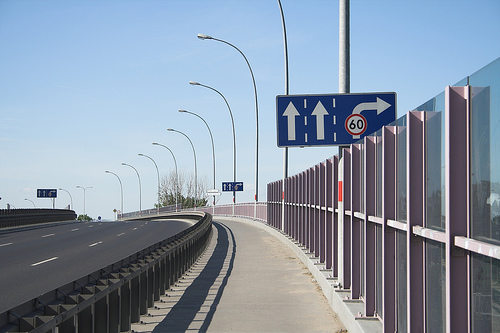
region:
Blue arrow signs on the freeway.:
[271, 85, 384, 146]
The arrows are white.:
[284, 98, 317, 135]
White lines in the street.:
[43, 227, 124, 259]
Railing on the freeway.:
[81, 216, 213, 280]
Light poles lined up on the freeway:
[128, 106, 326, 188]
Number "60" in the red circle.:
[344, 113, 367, 143]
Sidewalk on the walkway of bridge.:
[221, 195, 331, 331]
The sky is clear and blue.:
[44, 30, 229, 91]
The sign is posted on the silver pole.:
[268, 17, 400, 136]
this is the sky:
[21, 5, 84, 49]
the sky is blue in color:
[45, 7, 135, 50]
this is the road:
[43, 226, 116, 254]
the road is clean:
[50, 218, 134, 249]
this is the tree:
[157, 178, 229, 214]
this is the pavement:
[240, 241, 269, 313]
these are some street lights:
[133, 0, 306, 175]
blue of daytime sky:
[9, 2, 496, 214]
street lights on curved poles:
[107, 0, 350, 210]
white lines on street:
[0, 218, 189, 299]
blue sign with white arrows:
[275, 91, 396, 146]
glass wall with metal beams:
[269, 64, 495, 330]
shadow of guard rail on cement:
[166, 214, 237, 331]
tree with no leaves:
[163, 174, 214, 211]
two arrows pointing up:
[281, 98, 327, 141]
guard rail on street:
[13, 207, 213, 331]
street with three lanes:
[0, 218, 187, 313]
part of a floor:
[266, 252, 282, 279]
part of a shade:
[222, 251, 236, 273]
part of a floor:
[241, 254, 282, 320]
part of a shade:
[185, 240, 246, 311]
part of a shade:
[202, 258, 244, 308]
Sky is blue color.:
[49, 38, 137, 135]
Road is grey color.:
[15, 215, 133, 302]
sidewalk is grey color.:
[205, 208, 307, 328]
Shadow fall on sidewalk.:
[137, 218, 253, 331]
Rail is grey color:
[76, 250, 187, 329]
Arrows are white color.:
[218, 73, 405, 198]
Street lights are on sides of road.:
[86, 40, 368, 226]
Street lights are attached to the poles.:
[121, 33, 358, 188]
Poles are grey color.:
[117, 35, 294, 214]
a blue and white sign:
[260, 82, 397, 150]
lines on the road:
[19, 191, 149, 280]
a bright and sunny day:
[43, 25, 488, 314]